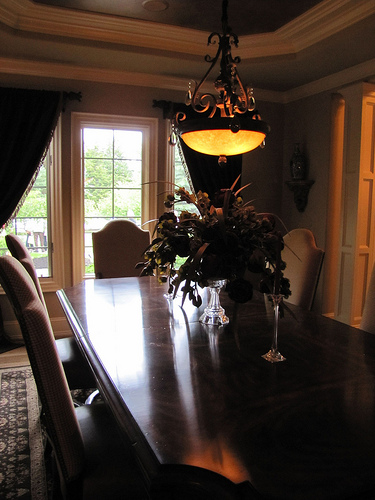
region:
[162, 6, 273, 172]
A lamp hanging from the ceiling.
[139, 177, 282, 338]
a vase of flowers on the table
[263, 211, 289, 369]
a candlestick holder.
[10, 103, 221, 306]
Three windows on the wall.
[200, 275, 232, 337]
a glass vase.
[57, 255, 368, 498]
A wooden table.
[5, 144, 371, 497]
A dining room.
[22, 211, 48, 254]
People are seen outside the window.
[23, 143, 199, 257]
Trees are outside the window.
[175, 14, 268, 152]
light hanging from ceiling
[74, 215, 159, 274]
chair in the room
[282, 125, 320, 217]
shelf with vase on wall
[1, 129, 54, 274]
window behind the chair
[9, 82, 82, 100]
rod of the curtain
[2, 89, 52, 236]
curtain on the window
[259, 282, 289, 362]
vase with plants in it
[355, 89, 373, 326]
doorway to other room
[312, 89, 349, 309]
beam in the room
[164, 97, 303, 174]
a light on the top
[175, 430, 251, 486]
light on the table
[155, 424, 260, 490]
light fallin on the table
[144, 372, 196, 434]
shadow on the table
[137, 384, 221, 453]
shadow falling on the table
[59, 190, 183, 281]
a chair in ground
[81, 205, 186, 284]
a chair in floor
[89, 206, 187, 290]
a chair near the table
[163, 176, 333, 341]
a flower in the table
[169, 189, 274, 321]
a jug on the table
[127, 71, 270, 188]
Orange light that is dim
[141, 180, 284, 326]
Flowers and a vase on table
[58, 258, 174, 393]
reflection on a wooden desk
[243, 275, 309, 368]
Glass candle holder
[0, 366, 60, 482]
oriental rug black with white patteren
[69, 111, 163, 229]
Large window letting in sunlight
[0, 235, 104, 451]
Pink chairs around table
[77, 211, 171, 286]
Pink chair and window in background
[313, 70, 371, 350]
white pillar with light in background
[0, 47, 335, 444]
Dinning room very dim and shaded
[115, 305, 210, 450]
this is a table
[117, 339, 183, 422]
the table is brown in color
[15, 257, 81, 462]
this is a chair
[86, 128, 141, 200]
this is a window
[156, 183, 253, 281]
this is a tree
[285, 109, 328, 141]
this is a wall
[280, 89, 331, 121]
the wall is white in color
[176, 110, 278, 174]
this is a light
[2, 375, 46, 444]
this is the floor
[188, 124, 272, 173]
the light is on